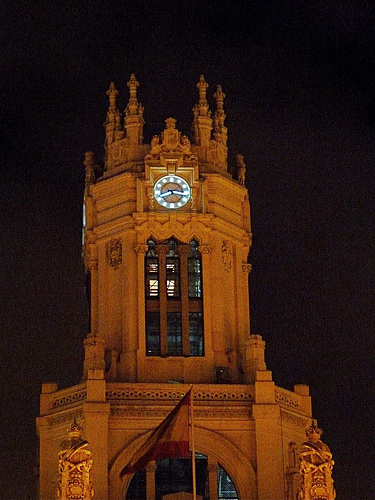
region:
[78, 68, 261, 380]
Ornate decorative clock tower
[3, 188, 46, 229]
Night sky above tower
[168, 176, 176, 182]
Number 12 on clock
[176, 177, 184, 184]
Number 1 on clock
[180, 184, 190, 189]
Number 2 on clock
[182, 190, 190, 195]
Number 3 on clock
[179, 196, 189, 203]
Number 4 on clock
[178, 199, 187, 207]
Number 5 on clock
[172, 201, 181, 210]
Number 6 on clock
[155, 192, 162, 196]
Number 9 on clock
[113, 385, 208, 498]
flag in the front of the building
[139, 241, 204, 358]
windows on the building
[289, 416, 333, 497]
budda decoration on the building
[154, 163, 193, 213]
clock on the tower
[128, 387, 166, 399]
decoration border on the building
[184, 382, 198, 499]
flag pole in front of the building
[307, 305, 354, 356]
nighttime outside of the building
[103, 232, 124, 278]
decorative piece on the building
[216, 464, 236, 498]
stairs inside the window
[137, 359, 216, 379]
orange wall of the building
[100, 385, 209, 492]
flag in front of building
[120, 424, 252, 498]
arched window behind the flag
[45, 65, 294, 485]
tower structure with clock on it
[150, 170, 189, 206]
clock on face of tower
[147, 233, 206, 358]
windows with pointed tops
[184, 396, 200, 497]
pole of the flag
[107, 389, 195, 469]
banner of the flag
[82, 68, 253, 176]
pointed structures on edge of tower top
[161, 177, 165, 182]
lit number on the clock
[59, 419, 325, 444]
crown structures on points near flag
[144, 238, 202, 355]
The windows right below the clock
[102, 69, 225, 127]
The four spike on top of the clock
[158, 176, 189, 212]
The illuminated clock face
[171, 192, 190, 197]
The small hand on the clock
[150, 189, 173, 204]
The large hand on the clock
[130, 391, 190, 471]
The red and yellow flag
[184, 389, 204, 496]
The flag pole holding up the flag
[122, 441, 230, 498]
The windows on the very bottom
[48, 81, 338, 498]
A tower with a clock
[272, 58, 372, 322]
The empty night sky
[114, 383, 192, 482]
red and white striped flag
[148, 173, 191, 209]
large white illuminated clock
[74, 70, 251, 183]
ornately carved top of a building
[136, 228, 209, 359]
beautiful black framed window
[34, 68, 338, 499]
light brown stone building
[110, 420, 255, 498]
arched window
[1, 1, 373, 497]
black sky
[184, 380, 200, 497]
white painted metal flag pole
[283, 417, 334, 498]
fancy carved stone in front of building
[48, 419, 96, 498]
fancy carved stone in front of building